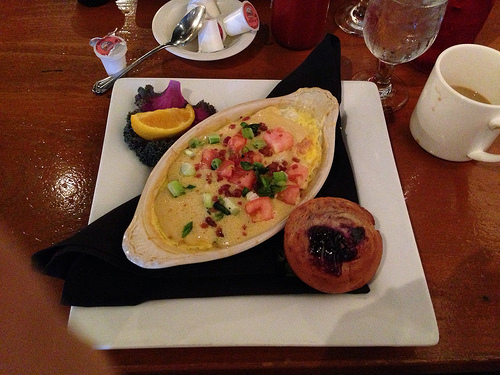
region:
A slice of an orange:
[123, 108, 203, 133]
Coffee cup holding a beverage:
[417, 48, 499, 169]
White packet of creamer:
[91, 31, 129, 71]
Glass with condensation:
[371, 0, 437, 101]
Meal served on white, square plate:
[70, 32, 470, 318]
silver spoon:
[82, 3, 239, 99]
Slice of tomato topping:
[241, 190, 290, 219]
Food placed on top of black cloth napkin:
[74, 65, 404, 295]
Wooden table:
[9, 4, 118, 272]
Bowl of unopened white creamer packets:
[157, 0, 271, 66]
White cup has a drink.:
[407, 41, 498, 165]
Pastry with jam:
[275, 191, 393, 302]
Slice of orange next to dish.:
[120, 95, 200, 143]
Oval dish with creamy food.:
[114, 81, 344, 268]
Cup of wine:
[352, 2, 449, 107]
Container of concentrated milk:
[80, 30, 133, 83]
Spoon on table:
[74, 4, 225, 101]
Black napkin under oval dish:
[30, 27, 387, 317]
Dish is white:
[55, 61, 443, 356]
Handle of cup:
[464, 112, 498, 166]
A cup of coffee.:
[409, 46, 499, 149]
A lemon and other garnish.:
[139, 77, 207, 130]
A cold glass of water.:
[359, 4, 427, 72]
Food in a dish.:
[181, 75, 298, 279]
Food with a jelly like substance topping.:
[286, 188, 385, 302]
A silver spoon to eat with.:
[98, 8, 211, 59]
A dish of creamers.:
[136, 0, 267, 74]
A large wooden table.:
[18, 6, 498, 350]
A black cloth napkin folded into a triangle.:
[112, 82, 405, 333]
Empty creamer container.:
[69, 29, 135, 74]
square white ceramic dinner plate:
[54, 44, 449, 359]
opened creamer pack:
[78, 24, 138, 80]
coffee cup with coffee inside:
[406, 22, 498, 184]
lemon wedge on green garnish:
[91, 71, 209, 160]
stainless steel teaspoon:
[77, 3, 227, 96]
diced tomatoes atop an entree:
[158, 77, 345, 242]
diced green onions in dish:
[136, 139, 296, 267]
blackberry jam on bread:
[264, 192, 399, 302]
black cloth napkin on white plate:
[23, 25, 428, 345]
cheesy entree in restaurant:
[115, 83, 365, 302]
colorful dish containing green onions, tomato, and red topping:
[158, 118, 308, 215]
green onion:
[181, 220, 195, 235]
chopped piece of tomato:
[244, 197, 276, 219]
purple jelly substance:
[306, 222, 369, 272]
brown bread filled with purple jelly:
[284, 197, 384, 291]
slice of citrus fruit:
[121, 104, 201, 136]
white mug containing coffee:
[408, 43, 498, 168]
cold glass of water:
[363, 0, 443, 108]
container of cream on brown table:
[77, 30, 129, 73]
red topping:
[207, 218, 217, 227]